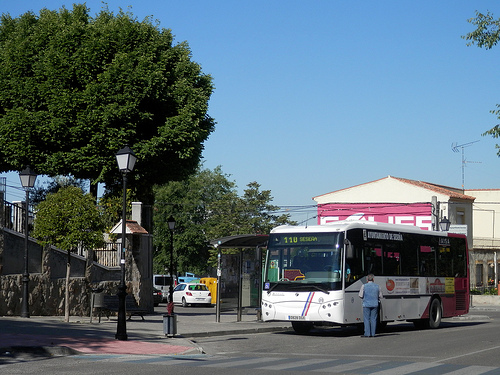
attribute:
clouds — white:
[216, 175, 498, 224]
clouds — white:
[262, 57, 436, 154]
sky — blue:
[249, 33, 499, 205]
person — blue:
[355, 276, 386, 342]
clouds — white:
[372, 119, 453, 156]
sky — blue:
[258, 23, 498, 188]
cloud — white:
[258, 127, 318, 158]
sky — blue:
[367, 52, 459, 151]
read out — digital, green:
[283, 234, 319, 243]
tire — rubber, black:
[422, 295, 447, 329]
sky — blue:
[193, 10, 493, 188]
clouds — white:
[233, 64, 283, 131]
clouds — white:
[237, 110, 425, 172]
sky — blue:
[207, 7, 471, 164]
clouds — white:
[246, 20, 317, 72]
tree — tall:
[20, 25, 198, 165]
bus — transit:
[244, 216, 409, 316]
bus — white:
[258, 218, 485, 345]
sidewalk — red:
[54, 335, 195, 355]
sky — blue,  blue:
[0, 3, 499, 232]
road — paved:
[220, 341, 493, 368]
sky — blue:
[269, 31, 365, 99]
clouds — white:
[3, 0, 495, 190]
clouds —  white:
[5, 0, 48, 14]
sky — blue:
[199, 15, 313, 64]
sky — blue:
[232, 23, 430, 155]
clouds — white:
[333, 48, 443, 146]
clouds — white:
[222, 19, 436, 162]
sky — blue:
[230, 61, 382, 170]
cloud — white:
[377, 54, 395, 72]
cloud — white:
[274, 179, 314, 202]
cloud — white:
[366, 119, 413, 157]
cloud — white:
[388, 123, 420, 146]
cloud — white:
[383, 50, 401, 68]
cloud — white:
[214, 119, 250, 157]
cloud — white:
[288, 168, 333, 189]